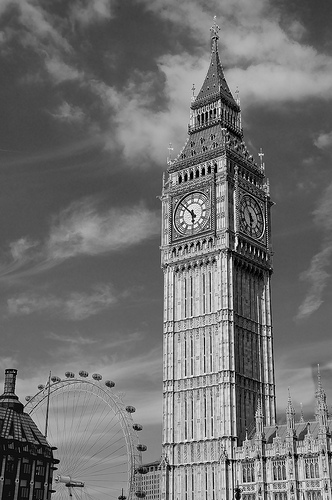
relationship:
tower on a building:
[156, 14, 278, 499] [155, 14, 331, 499]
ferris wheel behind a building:
[24, 370, 148, 499] [0, 369, 60, 500]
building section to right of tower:
[234, 363, 331, 499] [156, 14, 278, 499]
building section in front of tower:
[234, 363, 331, 499] [156, 14, 278, 499]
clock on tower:
[173, 192, 210, 236] [156, 14, 278, 499]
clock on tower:
[238, 195, 264, 239] [156, 14, 278, 499]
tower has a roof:
[156, 14, 278, 499] [167, 14, 266, 180]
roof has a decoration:
[167, 14, 266, 180] [166, 141, 175, 165]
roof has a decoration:
[167, 14, 266, 180] [258, 146, 265, 171]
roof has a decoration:
[167, 14, 266, 180] [190, 83, 196, 100]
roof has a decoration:
[167, 14, 266, 180] [235, 85, 240, 103]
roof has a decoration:
[167, 14, 266, 180] [210, 14, 222, 39]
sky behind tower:
[0, 1, 331, 500] [156, 14, 278, 499]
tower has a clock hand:
[156, 14, 278, 499] [179, 202, 197, 218]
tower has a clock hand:
[156, 14, 278, 499] [190, 209, 194, 224]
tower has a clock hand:
[156, 14, 278, 499] [244, 197, 254, 222]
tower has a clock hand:
[156, 14, 278, 499] [249, 214, 253, 227]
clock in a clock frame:
[173, 192, 210, 236] [168, 181, 216, 247]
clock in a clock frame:
[238, 195, 264, 239] [238, 186, 268, 247]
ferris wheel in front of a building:
[24, 370, 148, 499] [130, 459, 161, 499]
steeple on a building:
[253, 388, 265, 433] [155, 14, 331, 499]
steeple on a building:
[285, 386, 297, 428] [155, 14, 331, 499]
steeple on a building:
[313, 363, 329, 427] [155, 14, 331, 499]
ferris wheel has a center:
[24, 370, 148, 499] [54, 473, 72, 484]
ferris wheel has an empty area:
[24, 370, 148, 499] [116, 391, 129, 402]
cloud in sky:
[1, 190, 162, 291] [0, 1, 331, 500]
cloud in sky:
[0, 280, 163, 322] [0, 1, 331, 500]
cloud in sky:
[291, 235, 331, 323] [0, 1, 331, 500]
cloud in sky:
[308, 127, 331, 151] [0, 1, 331, 500]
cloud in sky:
[0, 0, 331, 172] [0, 1, 331, 500]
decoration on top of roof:
[210, 14, 222, 39] [167, 14, 266, 180]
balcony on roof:
[189, 99, 241, 130] [167, 14, 266, 180]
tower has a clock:
[156, 14, 278, 499] [173, 192, 210, 236]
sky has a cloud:
[0, 1, 331, 500] [0, 280, 163, 322]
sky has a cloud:
[0, 1, 331, 500] [1, 190, 162, 291]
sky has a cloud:
[0, 1, 331, 500] [291, 235, 331, 323]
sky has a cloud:
[0, 1, 331, 500] [308, 127, 331, 151]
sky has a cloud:
[0, 1, 331, 500] [0, 0, 331, 172]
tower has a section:
[156, 14, 278, 499] [156, 155, 276, 271]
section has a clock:
[156, 155, 276, 271] [173, 192, 210, 236]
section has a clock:
[156, 155, 276, 271] [238, 195, 264, 239]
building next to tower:
[0, 369, 60, 500] [156, 14, 278, 499]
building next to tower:
[130, 459, 161, 499] [156, 14, 278, 499]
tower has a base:
[156, 14, 278, 499] [159, 250, 277, 500]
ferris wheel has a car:
[24, 370, 148, 499] [105, 380, 115, 388]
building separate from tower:
[0, 369, 60, 500] [156, 14, 278, 499]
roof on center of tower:
[167, 14, 266, 180] [156, 14, 278, 499]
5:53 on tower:
[172, 190, 264, 238] [156, 14, 278, 499]